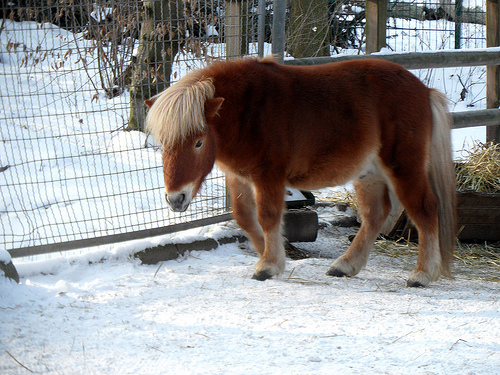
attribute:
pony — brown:
[115, 35, 479, 327]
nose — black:
[162, 190, 189, 212]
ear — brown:
[196, 80, 230, 133]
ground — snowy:
[148, 288, 415, 370]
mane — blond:
[139, 77, 215, 139]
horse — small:
[247, 251, 447, 301]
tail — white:
[416, 77, 476, 284]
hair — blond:
[129, 68, 216, 143]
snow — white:
[143, 292, 369, 360]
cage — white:
[8, 5, 286, 262]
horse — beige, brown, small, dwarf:
[142, 58, 466, 290]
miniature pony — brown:
[144, 56, 459, 293]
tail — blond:
[414, 85, 477, 297]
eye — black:
[192, 137, 204, 152]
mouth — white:
[138, 181, 213, 233]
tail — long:
[396, 75, 481, 287]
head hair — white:
[146, 84, 206, 142]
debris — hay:
[119, 271, 321, 359]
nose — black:
[169, 198, 183, 213]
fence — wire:
[3, 7, 498, 275]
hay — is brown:
[452, 139, 499, 191]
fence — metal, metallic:
[8, 0, 488, 245]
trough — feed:
[454, 144, 499, 241]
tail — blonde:
[415, 93, 467, 269]